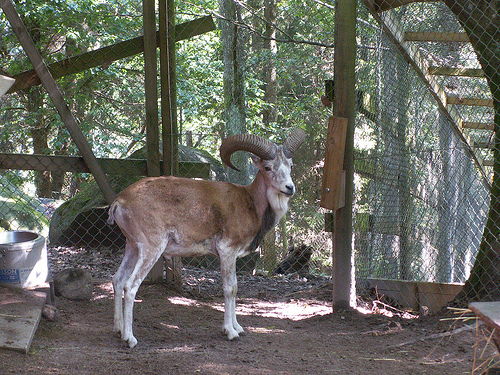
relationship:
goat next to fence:
[105, 128, 293, 348] [8, 12, 499, 297]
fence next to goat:
[8, 12, 499, 297] [105, 128, 293, 348]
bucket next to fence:
[0, 228, 43, 304] [8, 12, 499, 297]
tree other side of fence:
[214, 3, 254, 191] [8, 12, 499, 297]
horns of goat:
[216, 119, 306, 162] [105, 128, 293, 348]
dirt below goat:
[7, 272, 478, 375] [105, 128, 293, 348]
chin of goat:
[263, 185, 300, 215] [105, 128, 293, 348]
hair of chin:
[262, 190, 291, 220] [263, 185, 300, 215]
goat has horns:
[105, 128, 293, 348] [216, 119, 306, 162]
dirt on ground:
[7, 272, 478, 375] [3, 253, 490, 372]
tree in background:
[214, 3, 254, 191] [11, 2, 499, 176]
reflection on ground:
[207, 291, 376, 324] [3, 253, 490, 372]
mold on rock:
[54, 147, 180, 219] [54, 133, 216, 245]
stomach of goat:
[166, 226, 220, 262] [105, 128, 293, 348]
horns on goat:
[216, 119, 306, 162] [105, 128, 293, 348]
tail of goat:
[96, 201, 128, 229] [105, 128, 293, 348]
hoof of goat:
[120, 320, 137, 346] [105, 128, 293, 348]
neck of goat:
[241, 174, 288, 212] [105, 128, 293, 348]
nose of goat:
[282, 184, 298, 192] [105, 128, 293, 348]